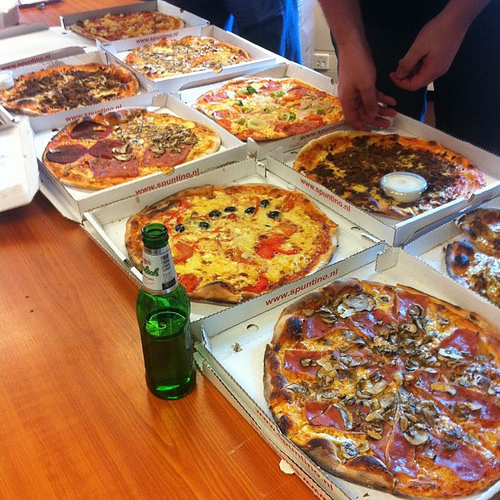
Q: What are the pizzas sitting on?
A: A table.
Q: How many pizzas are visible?
A: Nine.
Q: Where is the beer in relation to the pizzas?
A: To the left.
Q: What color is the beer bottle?
A: Green.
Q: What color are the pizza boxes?
A: White.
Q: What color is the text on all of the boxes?
A: Red.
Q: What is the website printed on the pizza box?
A: www.spunbino.nl.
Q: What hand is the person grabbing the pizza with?
A: His right.